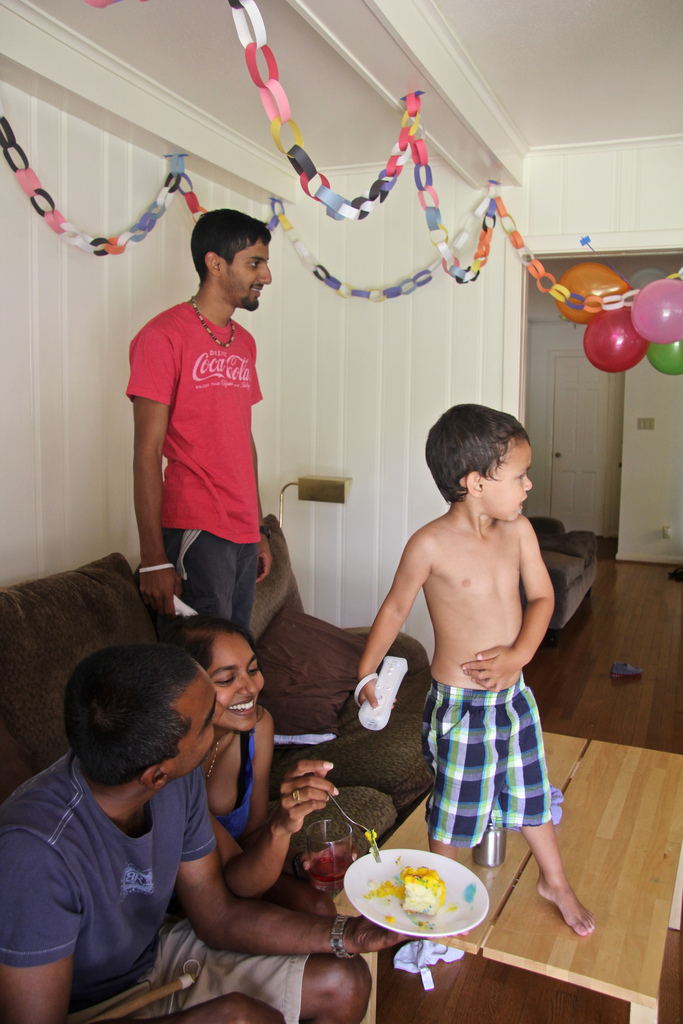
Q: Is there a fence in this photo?
A: No, there are no fences.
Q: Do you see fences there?
A: No, there are no fences.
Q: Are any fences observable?
A: No, there are no fences.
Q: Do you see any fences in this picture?
A: No, there are no fences.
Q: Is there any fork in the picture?
A: Yes, there is a fork.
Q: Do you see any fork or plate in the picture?
A: Yes, there is a fork.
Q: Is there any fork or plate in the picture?
A: Yes, there is a fork.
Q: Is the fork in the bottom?
A: Yes, the fork is in the bottom of the image.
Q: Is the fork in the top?
A: No, the fork is in the bottom of the image.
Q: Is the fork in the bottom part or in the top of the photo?
A: The fork is in the bottom of the image.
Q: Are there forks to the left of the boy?
A: Yes, there is a fork to the left of the boy.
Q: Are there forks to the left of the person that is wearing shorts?
A: Yes, there is a fork to the left of the boy.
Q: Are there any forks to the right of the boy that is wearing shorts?
A: No, the fork is to the left of the boy.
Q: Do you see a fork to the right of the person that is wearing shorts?
A: No, the fork is to the left of the boy.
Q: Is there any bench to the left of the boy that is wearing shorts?
A: No, there is a fork to the left of the boy.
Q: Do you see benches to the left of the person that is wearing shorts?
A: No, there is a fork to the left of the boy.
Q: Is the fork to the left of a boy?
A: Yes, the fork is to the left of a boy.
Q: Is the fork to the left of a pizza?
A: No, the fork is to the left of a boy.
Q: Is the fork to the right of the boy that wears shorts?
A: No, the fork is to the left of the boy.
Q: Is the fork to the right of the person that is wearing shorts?
A: No, the fork is to the left of the boy.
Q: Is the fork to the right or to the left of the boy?
A: The fork is to the left of the boy.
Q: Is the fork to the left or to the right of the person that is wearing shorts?
A: The fork is to the left of the boy.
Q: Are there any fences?
A: No, there are no fences.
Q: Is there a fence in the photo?
A: No, there are no fences.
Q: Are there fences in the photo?
A: No, there are no fences.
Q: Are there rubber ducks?
A: No, there are no rubber ducks.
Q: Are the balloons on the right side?
A: Yes, the balloons are on the right of the image.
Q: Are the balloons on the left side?
A: No, the balloons are on the right of the image.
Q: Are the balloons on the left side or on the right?
A: The balloons are on the right of the image.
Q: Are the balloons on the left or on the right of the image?
A: The balloons are on the right of the image.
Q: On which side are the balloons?
A: The balloons are on the right of the image.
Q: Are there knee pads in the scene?
A: No, there are no knee pads.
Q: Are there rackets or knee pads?
A: No, there are no knee pads or rackets.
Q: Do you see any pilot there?
A: No, there are no pilots.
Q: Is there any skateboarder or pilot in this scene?
A: No, there are no pilots or skateboarders.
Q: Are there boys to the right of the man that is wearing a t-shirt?
A: Yes, there is a boy to the right of the man.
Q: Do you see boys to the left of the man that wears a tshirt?
A: No, the boy is to the right of the man.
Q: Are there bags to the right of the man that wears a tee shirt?
A: No, there is a boy to the right of the man.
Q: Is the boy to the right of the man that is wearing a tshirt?
A: Yes, the boy is to the right of the man.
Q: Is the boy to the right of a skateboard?
A: No, the boy is to the right of the man.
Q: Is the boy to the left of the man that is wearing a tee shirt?
A: No, the boy is to the right of the man.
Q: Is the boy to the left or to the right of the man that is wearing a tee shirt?
A: The boy is to the right of the man.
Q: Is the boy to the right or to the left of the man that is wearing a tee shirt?
A: The boy is to the right of the man.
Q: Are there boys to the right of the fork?
A: Yes, there is a boy to the right of the fork.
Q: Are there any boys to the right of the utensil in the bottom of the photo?
A: Yes, there is a boy to the right of the fork.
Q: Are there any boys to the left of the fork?
A: No, the boy is to the right of the fork.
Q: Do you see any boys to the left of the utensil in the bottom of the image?
A: No, the boy is to the right of the fork.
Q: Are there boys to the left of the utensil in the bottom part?
A: No, the boy is to the right of the fork.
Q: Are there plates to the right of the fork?
A: No, there is a boy to the right of the fork.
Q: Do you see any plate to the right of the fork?
A: No, there is a boy to the right of the fork.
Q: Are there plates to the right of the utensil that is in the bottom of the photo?
A: No, there is a boy to the right of the fork.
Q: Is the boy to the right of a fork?
A: Yes, the boy is to the right of a fork.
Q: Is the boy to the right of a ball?
A: No, the boy is to the right of a fork.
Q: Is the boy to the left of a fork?
A: No, the boy is to the right of a fork.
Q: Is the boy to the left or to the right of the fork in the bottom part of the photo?
A: The boy is to the right of the fork.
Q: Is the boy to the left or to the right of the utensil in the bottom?
A: The boy is to the right of the fork.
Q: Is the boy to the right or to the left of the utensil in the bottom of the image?
A: The boy is to the right of the fork.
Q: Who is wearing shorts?
A: The boy is wearing shorts.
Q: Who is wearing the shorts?
A: The boy is wearing shorts.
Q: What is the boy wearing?
A: The boy is wearing shorts.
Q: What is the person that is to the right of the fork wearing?
A: The boy is wearing shorts.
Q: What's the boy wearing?
A: The boy is wearing shorts.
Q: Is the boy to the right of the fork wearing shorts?
A: Yes, the boy is wearing shorts.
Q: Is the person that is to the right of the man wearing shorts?
A: Yes, the boy is wearing shorts.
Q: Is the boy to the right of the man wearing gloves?
A: No, the boy is wearing shorts.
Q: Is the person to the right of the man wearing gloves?
A: No, the boy is wearing shorts.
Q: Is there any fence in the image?
A: No, there are no fences.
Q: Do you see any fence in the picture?
A: No, there are no fences.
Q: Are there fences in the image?
A: No, there are no fences.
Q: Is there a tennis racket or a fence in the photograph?
A: No, there are no fences or rackets.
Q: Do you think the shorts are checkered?
A: Yes, the shorts are checkered.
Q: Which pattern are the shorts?
A: The shorts are checkered.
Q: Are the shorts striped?
A: No, the shorts are checkered.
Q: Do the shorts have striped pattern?
A: No, the shorts are checkered.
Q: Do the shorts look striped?
A: No, the shorts are checkered.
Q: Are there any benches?
A: No, there are no benches.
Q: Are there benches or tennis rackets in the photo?
A: No, there are no benches or tennis rackets.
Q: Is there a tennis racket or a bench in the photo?
A: No, there are no benches or rackets.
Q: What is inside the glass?
A: The liquid is inside the glass.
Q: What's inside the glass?
A: The liquid is inside the glass.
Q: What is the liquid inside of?
A: The liquid is inside the glass.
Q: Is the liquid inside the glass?
A: Yes, the liquid is inside the glass.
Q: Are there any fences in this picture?
A: No, there are no fences.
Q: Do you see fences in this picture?
A: No, there are no fences.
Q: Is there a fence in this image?
A: No, there are no fences.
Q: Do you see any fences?
A: No, there are no fences.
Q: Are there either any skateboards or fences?
A: No, there are no fences or skateboards.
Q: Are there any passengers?
A: No, there are no passengers.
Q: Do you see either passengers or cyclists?
A: No, there are no passengers or cyclists.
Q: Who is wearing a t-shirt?
A: The man is wearing a t-shirt.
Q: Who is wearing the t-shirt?
A: The man is wearing a t-shirt.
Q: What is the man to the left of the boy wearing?
A: The man is wearing a tshirt.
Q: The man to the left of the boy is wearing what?
A: The man is wearing a tshirt.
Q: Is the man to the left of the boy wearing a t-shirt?
A: Yes, the man is wearing a t-shirt.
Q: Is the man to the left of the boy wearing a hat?
A: No, the man is wearing a t-shirt.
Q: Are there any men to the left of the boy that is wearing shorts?
A: Yes, there is a man to the left of the boy.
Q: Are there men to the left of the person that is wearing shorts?
A: Yes, there is a man to the left of the boy.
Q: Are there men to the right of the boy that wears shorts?
A: No, the man is to the left of the boy.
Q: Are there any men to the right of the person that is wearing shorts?
A: No, the man is to the left of the boy.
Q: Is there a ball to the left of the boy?
A: No, there is a man to the left of the boy.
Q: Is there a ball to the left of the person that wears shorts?
A: No, there is a man to the left of the boy.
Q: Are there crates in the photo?
A: No, there are no crates.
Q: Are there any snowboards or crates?
A: No, there are no crates or snowboards.